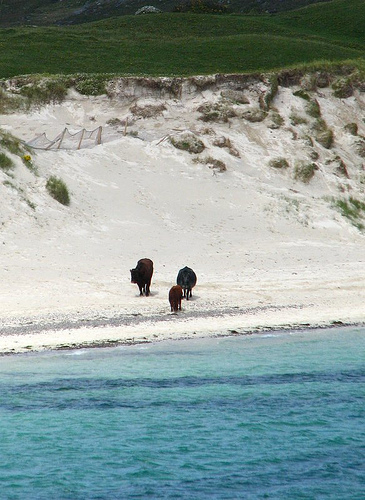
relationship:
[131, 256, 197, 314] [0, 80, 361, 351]
bison on plain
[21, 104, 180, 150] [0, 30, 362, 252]
fence on hillside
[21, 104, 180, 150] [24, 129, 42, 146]
fence has post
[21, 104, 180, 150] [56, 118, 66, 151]
fence has post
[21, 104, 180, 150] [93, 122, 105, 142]
fence has post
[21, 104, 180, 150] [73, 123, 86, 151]
fence has post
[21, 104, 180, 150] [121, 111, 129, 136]
fence has post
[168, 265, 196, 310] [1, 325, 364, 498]
three cows near ocean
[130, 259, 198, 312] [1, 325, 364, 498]
three cows near ocean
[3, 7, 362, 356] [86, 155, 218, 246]
hillside covered with snow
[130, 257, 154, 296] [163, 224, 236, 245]
bison standing on snow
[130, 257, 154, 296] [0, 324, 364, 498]
bison standing near ocean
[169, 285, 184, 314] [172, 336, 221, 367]
bison standing near water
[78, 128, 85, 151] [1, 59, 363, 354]
post in ground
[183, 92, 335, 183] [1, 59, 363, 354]
rock on ground